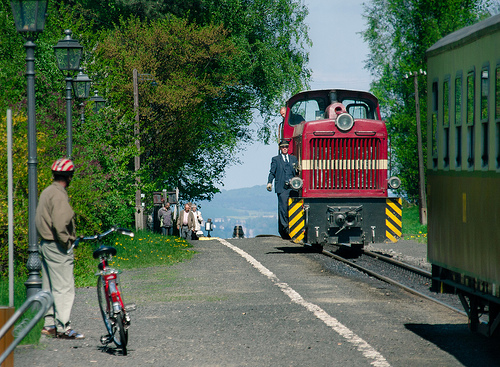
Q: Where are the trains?
A: On the track.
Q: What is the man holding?
A: A bicycle.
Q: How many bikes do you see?
A: 1.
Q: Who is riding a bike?
A: No one.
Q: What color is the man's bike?
A: Red.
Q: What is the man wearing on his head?
A: A bike helmet.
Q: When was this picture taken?
A: Daytime.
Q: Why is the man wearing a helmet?
A: For safety.